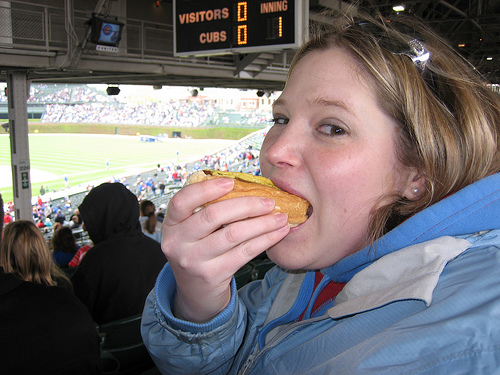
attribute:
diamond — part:
[1, 123, 243, 203]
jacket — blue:
[139, 172, 500, 373]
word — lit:
[179, 5, 231, 26]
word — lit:
[199, 30, 230, 45]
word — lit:
[255, 0, 289, 14]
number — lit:
[275, 17, 286, 40]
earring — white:
[412, 188, 422, 195]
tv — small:
[90, 14, 127, 47]